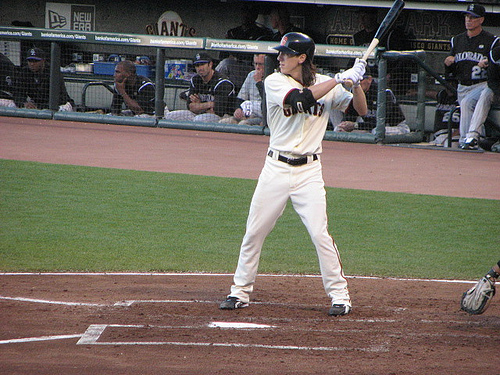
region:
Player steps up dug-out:
[401, 2, 497, 152]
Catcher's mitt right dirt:
[451, 257, 496, 323]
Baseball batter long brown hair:
[260, 60, 330, 87]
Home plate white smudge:
[160, 295, 315, 355]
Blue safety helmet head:
[255, 30, 320, 55]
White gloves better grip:
[326, 47, 371, 88]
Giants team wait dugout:
[6, 10, 251, 130]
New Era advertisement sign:
[45, 4, 100, 39]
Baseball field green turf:
[3, 182, 204, 261]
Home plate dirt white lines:
[4, 312, 409, 372]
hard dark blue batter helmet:
[268, 22, 319, 68]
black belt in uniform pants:
[261, 139, 346, 174]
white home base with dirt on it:
[182, 302, 314, 347]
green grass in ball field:
[24, 169, 158, 263]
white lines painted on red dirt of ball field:
[18, 257, 131, 369]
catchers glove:
[443, 263, 496, 309]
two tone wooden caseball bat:
[347, 1, 410, 108]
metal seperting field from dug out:
[21, 17, 341, 144]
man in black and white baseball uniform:
[441, 3, 498, 170]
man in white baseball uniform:
[247, 33, 384, 314]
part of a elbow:
[301, 96, 310, 108]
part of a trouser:
[264, 205, 271, 219]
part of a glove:
[468, 287, 483, 312]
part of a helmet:
[292, 37, 305, 41]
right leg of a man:
[321, 241, 341, 296]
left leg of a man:
[238, 243, 256, 299]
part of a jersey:
[295, 117, 303, 125]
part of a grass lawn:
[107, 174, 144, 221]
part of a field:
[163, 299, 205, 342]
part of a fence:
[126, 94, 138, 108]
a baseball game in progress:
[2, 0, 497, 369]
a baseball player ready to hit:
[217, 0, 409, 315]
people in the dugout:
[1, 0, 497, 150]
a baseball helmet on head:
[274, 29, 316, 63]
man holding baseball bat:
[333, 0, 410, 86]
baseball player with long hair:
[274, 30, 318, 87]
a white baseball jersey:
[262, 71, 350, 152]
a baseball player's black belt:
[264, 146, 320, 166]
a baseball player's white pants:
[227, 149, 351, 307]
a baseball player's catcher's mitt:
[459, 276, 496, 315]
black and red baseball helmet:
[271, 29, 315, 64]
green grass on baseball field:
[17, 167, 205, 269]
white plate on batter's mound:
[206, 311, 283, 335]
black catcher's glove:
[458, 272, 495, 318]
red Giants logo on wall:
[144, 19, 196, 39]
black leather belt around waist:
[265, 142, 320, 167]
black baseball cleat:
[217, 290, 252, 311]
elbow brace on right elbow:
[285, 87, 320, 113]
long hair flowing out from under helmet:
[297, 55, 319, 86]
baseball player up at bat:
[213, 1, 403, 318]